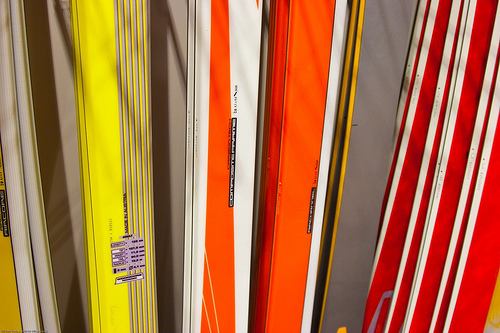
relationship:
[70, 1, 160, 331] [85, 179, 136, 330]
stripe on wall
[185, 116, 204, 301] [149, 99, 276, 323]
stripe on wall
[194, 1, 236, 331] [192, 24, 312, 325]
orange stripe on wall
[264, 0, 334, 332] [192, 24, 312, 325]
orange stripe on wall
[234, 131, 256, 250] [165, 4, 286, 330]
white stripe on wall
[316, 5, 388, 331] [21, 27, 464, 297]
stripe on wall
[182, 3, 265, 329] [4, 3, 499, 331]
stripe on wall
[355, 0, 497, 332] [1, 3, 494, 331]
red blints on display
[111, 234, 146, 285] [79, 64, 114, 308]
label on board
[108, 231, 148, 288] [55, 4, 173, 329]
label on blinds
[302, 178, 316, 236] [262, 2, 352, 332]
label on blind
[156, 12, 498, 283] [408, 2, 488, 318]
vertical blind has connector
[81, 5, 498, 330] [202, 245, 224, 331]
vertical blinds has string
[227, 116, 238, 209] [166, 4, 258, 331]
white sign on board